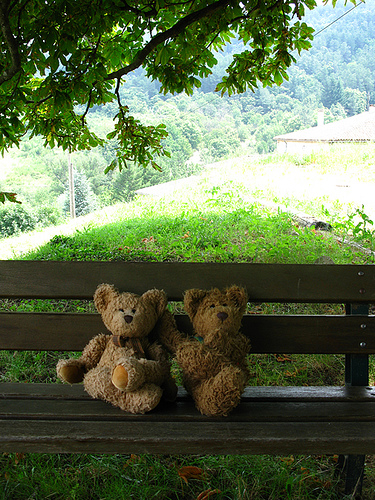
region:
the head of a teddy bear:
[92, 279, 171, 342]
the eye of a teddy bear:
[114, 303, 125, 315]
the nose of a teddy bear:
[122, 312, 134, 325]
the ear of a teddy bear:
[141, 285, 169, 319]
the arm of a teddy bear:
[51, 331, 111, 387]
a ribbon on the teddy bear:
[110, 330, 151, 357]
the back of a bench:
[0, 255, 372, 360]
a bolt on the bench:
[357, 317, 372, 333]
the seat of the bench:
[0, 381, 374, 457]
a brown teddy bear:
[153, 281, 251, 419]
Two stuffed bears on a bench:
[54, 261, 274, 423]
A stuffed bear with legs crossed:
[65, 279, 171, 415]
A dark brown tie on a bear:
[111, 332, 150, 354]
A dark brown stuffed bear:
[179, 285, 258, 425]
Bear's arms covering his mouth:
[185, 291, 251, 370]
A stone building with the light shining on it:
[269, 106, 372, 164]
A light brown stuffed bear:
[64, 279, 173, 408]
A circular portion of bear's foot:
[112, 365, 131, 389]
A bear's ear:
[96, 284, 114, 310]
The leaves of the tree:
[115, 107, 167, 171]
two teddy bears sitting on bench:
[50, 269, 255, 416]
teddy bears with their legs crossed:
[56, 272, 256, 415]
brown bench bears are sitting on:
[4, 259, 374, 483]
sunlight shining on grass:
[2, 126, 364, 219]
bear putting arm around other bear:
[153, 281, 262, 412]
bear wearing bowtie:
[59, 280, 174, 414]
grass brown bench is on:
[4, 188, 365, 499]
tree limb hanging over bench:
[2, 1, 303, 170]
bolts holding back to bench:
[349, 265, 371, 346]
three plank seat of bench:
[2, 375, 373, 439]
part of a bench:
[310, 424, 322, 428]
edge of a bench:
[62, 436, 73, 456]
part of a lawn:
[255, 466, 268, 471]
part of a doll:
[130, 376, 136, 382]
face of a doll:
[201, 294, 222, 334]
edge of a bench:
[281, 428, 296, 436]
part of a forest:
[208, 105, 217, 120]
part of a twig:
[267, 43, 282, 55]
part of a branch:
[120, 111, 141, 144]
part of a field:
[61, 468, 78, 495]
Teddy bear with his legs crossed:
[55, 286, 170, 415]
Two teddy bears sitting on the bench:
[55, 281, 262, 415]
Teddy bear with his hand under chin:
[157, 288, 270, 417]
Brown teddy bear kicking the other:
[56, 286, 252, 418]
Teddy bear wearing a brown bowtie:
[111, 332, 146, 353]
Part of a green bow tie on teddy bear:
[193, 334, 207, 344]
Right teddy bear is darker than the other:
[56, 285, 247, 417]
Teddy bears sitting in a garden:
[58, 285, 244, 414]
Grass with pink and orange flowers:
[114, 215, 210, 253]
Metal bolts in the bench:
[358, 323, 369, 349]